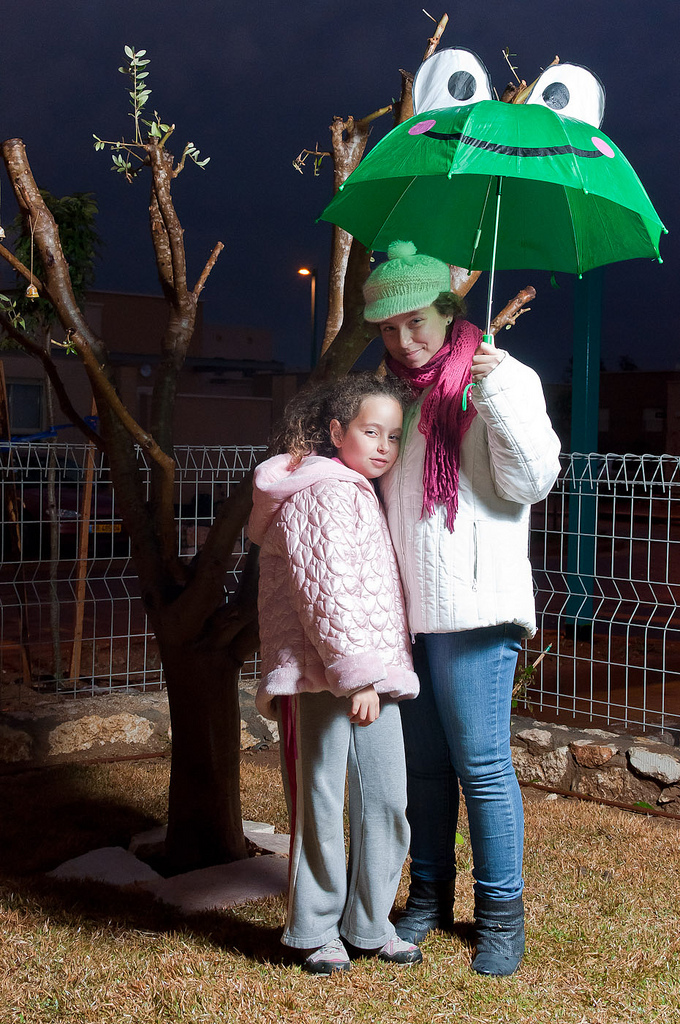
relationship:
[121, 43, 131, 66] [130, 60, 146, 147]
leaf on stem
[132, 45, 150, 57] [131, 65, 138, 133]
leaf on stem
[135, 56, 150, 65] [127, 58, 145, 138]
leaf on stem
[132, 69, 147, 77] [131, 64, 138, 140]
leaf on stem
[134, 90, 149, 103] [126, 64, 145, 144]
leaf on stem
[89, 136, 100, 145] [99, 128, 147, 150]
leaf on stem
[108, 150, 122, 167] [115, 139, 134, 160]
leaf on stem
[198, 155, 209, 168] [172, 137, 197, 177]
leaf on stem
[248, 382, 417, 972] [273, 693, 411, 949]
girl has pants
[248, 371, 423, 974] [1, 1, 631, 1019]
girl posing for a picture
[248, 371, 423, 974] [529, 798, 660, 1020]
girl standing in grass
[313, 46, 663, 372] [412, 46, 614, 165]
umbrella shaped like a frog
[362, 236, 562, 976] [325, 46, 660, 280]
lady holding an umbrella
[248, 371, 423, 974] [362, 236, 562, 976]
girl standing next to lady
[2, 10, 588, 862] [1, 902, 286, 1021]
tree planted in ground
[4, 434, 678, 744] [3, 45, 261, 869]
fence enclosing tree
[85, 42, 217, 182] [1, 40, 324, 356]
leaves growing on tree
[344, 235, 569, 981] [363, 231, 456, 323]
lady wearing a hat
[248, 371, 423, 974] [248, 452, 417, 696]
girl wearing a coat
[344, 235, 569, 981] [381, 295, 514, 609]
lady wearing a scarf